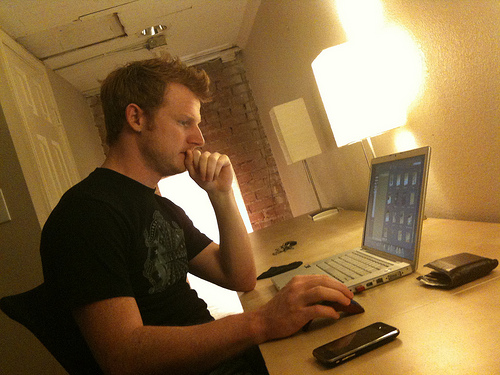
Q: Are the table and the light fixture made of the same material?
A: No, the table is made of wood and the light fixture is made of metal.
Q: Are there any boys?
A: No, there are no boys.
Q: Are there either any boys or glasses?
A: No, there are no boys or glasses.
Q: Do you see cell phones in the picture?
A: Yes, there is a cell phone.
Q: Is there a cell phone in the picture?
A: Yes, there is a cell phone.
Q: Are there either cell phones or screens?
A: Yes, there is a cell phone.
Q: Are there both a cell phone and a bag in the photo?
A: No, there is a cell phone but no bags.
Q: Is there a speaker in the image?
A: No, there are no speakers.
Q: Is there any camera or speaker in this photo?
A: No, there are no speakers or cameras.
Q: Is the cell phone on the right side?
A: Yes, the cell phone is on the right of the image.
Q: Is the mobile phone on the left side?
A: No, the mobile phone is on the right of the image.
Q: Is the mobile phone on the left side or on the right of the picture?
A: The mobile phone is on the right of the image.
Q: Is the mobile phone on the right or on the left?
A: The mobile phone is on the right of the image.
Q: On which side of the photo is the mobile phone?
A: The mobile phone is on the right of the image.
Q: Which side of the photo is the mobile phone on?
A: The mobile phone is on the right of the image.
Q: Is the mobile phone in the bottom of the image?
A: Yes, the mobile phone is in the bottom of the image.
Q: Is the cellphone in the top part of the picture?
A: No, the cellphone is in the bottom of the image.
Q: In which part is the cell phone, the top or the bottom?
A: The cell phone is in the bottom of the image.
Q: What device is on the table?
A: The device is a cell phone.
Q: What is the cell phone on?
A: The cell phone is on the table.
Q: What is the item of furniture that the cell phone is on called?
A: The piece of furniture is a table.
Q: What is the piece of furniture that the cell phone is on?
A: The piece of furniture is a table.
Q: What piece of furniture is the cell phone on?
A: The cell phone is on the table.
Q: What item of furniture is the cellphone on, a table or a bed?
A: The cellphone is on a table.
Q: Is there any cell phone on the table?
A: Yes, there is a cell phone on the table.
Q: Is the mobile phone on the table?
A: Yes, the mobile phone is on the table.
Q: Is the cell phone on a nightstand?
A: No, the cell phone is on the table.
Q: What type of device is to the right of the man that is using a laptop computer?
A: The device is a cell phone.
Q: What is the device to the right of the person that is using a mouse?
A: The device is a cell phone.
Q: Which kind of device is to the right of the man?
A: The device is a cell phone.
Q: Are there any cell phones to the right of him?
A: Yes, there is a cell phone to the right of the man.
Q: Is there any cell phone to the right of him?
A: Yes, there is a cell phone to the right of the man.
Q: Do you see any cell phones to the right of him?
A: Yes, there is a cell phone to the right of the man.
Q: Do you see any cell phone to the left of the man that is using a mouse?
A: No, the cell phone is to the right of the man.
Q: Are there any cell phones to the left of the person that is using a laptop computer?
A: No, the cell phone is to the right of the man.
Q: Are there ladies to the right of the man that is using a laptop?
A: No, there is a cell phone to the right of the man.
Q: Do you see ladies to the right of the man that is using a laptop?
A: No, there is a cell phone to the right of the man.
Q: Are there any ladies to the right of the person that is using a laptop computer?
A: No, there is a cell phone to the right of the man.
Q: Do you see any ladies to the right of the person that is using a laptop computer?
A: No, there is a cell phone to the right of the man.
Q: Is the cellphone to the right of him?
A: Yes, the cellphone is to the right of a man.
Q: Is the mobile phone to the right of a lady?
A: No, the mobile phone is to the right of a man.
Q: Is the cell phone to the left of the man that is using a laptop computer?
A: No, the cell phone is to the right of the man.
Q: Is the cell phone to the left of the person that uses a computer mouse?
A: No, the cell phone is to the right of the man.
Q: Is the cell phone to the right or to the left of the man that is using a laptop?
A: The cell phone is to the right of the man.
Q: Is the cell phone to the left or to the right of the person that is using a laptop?
A: The cell phone is to the right of the man.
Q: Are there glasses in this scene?
A: No, there are no glasses.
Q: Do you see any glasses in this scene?
A: No, there are no glasses.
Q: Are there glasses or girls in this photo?
A: No, there are no glasses or girls.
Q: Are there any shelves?
A: No, there are no shelves.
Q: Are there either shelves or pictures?
A: No, there are no shelves or pictures.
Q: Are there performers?
A: No, there are no performers.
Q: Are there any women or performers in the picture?
A: No, there are no performers or women.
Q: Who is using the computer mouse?
A: The man is using the computer mouse.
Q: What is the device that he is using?
A: The device is a computer mouse.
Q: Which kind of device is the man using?
A: The man is using a mouse.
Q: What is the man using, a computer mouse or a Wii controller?
A: The man is using a computer mouse.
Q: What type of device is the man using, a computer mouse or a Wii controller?
A: The man is using a computer mouse.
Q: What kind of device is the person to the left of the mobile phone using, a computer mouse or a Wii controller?
A: The man is using a computer mouse.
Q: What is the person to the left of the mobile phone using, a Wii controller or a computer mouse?
A: The man is using a computer mouse.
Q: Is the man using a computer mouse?
A: Yes, the man is using a computer mouse.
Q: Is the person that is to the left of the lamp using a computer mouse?
A: Yes, the man is using a computer mouse.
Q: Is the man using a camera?
A: No, the man is using a computer mouse.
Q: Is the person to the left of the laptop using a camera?
A: No, the man is using a computer mouse.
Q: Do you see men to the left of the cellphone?
A: Yes, there is a man to the left of the cellphone.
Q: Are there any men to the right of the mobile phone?
A: No, the man is to the left of the mobile phone.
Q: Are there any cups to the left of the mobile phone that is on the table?
A: No, there is a man to the left of the cell phone.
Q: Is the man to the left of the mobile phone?
A: Yes, the man is to the left of the mobile phone.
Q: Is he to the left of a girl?
A: No, the man is to the left of the mobile phone.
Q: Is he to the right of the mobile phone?
A: No, the man is to the left of the mobile phone.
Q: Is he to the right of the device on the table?
A: No, the man is to the left of the mobile phone.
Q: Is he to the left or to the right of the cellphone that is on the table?
A: The man is to the left of the cellphone.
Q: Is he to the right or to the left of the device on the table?
A: The man is to the left of the cellphone.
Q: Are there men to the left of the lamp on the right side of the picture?
A: Yes, there is a man to the left of the lamp.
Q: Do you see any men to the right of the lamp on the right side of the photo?
A: No, the man is to the left of the lamp.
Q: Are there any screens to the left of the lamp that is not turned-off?
A: No, there is a man to the left of the lamp.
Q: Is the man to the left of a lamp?
A: Yes, the man is to the left of a lamp.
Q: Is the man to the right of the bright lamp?
A: No, the man is to the left of the lamp.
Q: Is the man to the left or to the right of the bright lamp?
A: The man is to the left of the lamp.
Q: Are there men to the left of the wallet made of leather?
A: Yes, there is a man to the left of the wallet.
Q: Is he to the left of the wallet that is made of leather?
A: Yes, the man is to the left of the wallet.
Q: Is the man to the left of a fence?
A: No, the man is to the left of the wallet.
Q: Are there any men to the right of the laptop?
A: No, the man is to the left of the laptop.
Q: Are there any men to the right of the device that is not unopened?
A: No, the man is to the left of the laptop.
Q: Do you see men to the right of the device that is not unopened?
A: No, the man is to the left of the laptop.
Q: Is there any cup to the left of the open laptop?
A: No, there is a man to the left of the laptop computer.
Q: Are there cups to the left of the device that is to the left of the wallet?
A: No, there is a man to the left of the laptop computer.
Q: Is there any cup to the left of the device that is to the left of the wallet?
A: No, there is a man to the left of the laptop computer.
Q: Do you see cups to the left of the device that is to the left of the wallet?
A: No, there is a man to the left of the laptop computer.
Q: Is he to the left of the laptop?
A: Yes, the man is to the left of the laptop.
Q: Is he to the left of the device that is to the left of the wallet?
A: Yes, the man is to the left of the laptop.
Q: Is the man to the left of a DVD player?
A: No, the man is to the left of the laptop.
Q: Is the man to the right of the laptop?
A: No, the man is to the left of the laptop.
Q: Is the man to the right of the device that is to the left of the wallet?
A: No, the man is to the left of the laptop.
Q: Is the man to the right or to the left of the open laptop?
A: The man is to the left of the laptop.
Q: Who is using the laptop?
A: The man is using the laptop.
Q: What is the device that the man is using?
A: The device is a laptop.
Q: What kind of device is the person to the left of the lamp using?
A: The man is using a laptop.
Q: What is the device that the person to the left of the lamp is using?
A: The device is a laptop.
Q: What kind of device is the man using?
A: The man is using a laptop.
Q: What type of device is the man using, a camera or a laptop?
A: The man is using a laptop.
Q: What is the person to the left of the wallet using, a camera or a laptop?
A: The man is using a laptop.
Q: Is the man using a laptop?
A: Yes, the man is using a laptop.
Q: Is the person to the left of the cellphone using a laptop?
A: Yes, the man is using a laptop.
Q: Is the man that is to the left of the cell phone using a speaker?
A: No, the man is using a laptop.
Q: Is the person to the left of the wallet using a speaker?
A: No, the man is using a laptop.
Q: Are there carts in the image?
A: No, there are no carts.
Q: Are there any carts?
A: No, there are no carts.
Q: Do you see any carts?
A: No, there are no carts.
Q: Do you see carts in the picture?
A: No, there are no carts.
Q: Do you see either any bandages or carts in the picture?
A: No, there are no carts or bandages.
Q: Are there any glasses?
A: No, there are no glasses.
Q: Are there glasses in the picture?
A: No, there are no glasses.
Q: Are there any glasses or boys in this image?
A: No, there are no glasses or boys.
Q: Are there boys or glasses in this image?
A: No, there are no glasses or boys.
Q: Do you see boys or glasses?
A: No, there are no glasses or boys.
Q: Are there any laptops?
A: Yes, there is a laptop.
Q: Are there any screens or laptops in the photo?
A: Yes, there is a laptop.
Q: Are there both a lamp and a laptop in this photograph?
A: Yes, there are both a laptop and a lamp.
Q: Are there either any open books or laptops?
A: Yes, there is an open laptop.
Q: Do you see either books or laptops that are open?
A: Yes, the laptop is open.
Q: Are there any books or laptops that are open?
A: Yes, the laptop is open.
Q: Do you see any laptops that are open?
A: Yes, there is an open laptop.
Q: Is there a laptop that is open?
A: Yes, there is a laptop that is open.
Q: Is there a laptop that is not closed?
A: Yes, there is a open laptop.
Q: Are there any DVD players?
A: No, there are no DVD players.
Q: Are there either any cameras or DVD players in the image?
A: No, there are no DVD players or cameras.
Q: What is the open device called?
A: The device is a laptop.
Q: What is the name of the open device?
A: The device is a laptop.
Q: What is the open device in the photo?
A: The device is a laptop.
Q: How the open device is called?
A: The device is a laptop.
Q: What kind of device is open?
A: The device is a laptop.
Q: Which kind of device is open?
A: The device is a laptop.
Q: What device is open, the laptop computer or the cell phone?
A: The laptop computer is open.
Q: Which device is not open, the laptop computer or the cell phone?
A: The cell phone is not open.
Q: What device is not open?
A: The device is a cell phone.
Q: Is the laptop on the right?
A: Yes, the laptop is on the right of the image.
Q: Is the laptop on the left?
A: No, the laptop is on the right of the image.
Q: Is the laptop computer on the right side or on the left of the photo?
A: The laptop computer is on the right of the image.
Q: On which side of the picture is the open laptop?
A: The laptop computer is on the right of the image.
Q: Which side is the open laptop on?
A: The laptop computer is on the right of the image.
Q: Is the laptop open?
A: Yes, the laptop is open.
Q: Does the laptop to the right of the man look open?
A: Yes, the laptop computer is open.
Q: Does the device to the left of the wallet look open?
A: Yes, the laptop computer is open.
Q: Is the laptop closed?
A: No, the laptop is open.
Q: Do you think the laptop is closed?
A: No, the laptop is open.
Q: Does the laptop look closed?
A: No, the laptop is open.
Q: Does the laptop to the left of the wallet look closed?
A: No, the laptop is open.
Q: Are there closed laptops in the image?
A: No, there is a laptop but it is open.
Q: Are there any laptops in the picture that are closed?
A: No, there is a laptop but it is open.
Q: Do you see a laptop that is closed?
A: No, there is a laptop but it is open.